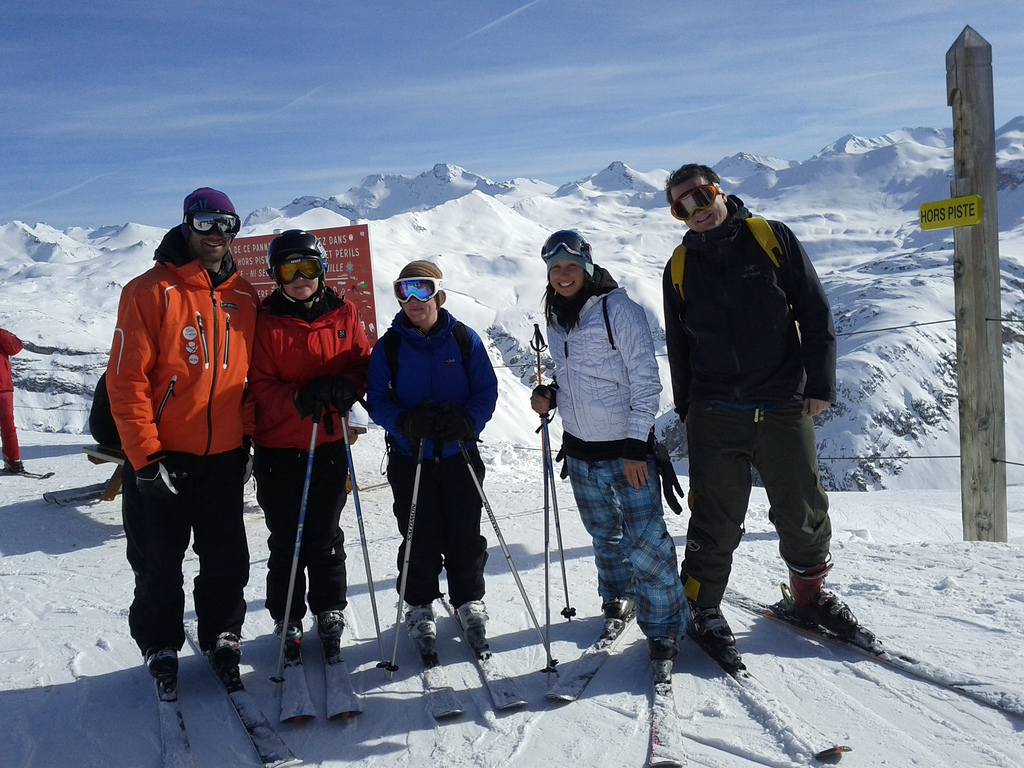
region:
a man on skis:
[108, 188, 301, 765]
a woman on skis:
[250, 226, 367, 727]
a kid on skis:
[364, 264, 523, 713]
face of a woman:
[544, 258, 583, 293]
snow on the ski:
[648, 671, 667, 767]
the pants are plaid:
[569, 453, 680, 644]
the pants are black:
[684, 438, 833, 582]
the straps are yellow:
[672, 211, 780, 292]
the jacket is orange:
[106, 226, 249, 471]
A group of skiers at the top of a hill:
[54, 161, 874, 678]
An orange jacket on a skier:
[106, 266, 252, 448]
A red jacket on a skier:
[257, 287, 366, 431]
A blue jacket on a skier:
[367, 307, 500, 456]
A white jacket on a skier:
[532, 290, 654, 445]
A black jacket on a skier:
[659, 211, 834, 401]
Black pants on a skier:
[118, 446, 252, 644]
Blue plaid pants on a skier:
[560, 449, 687, 640]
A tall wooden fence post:
[942, 22, 1012, 535]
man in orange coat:
[69, 129, 262, 702]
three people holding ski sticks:
[243, 229, 676, 670]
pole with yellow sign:
[888, 17, 1010, 559]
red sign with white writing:
[243, 227, 379, 330]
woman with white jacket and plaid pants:
[520, 205, 698, 686]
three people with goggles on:
[94, 205, 513, 717]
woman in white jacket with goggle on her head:
[502, 236, 680, 590]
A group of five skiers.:
[70, 164, 884, 766]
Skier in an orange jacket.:
[93, 186, 296, 766]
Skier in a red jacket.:
[250, 222, 388, 731]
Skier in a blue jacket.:
[340, 259, 537, 721]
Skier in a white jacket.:
[522, 218, 693, 766]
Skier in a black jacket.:
[655, 148, 1020, 760]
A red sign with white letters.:
[198, 215, 382, 356]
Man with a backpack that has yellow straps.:
[642, 151, 890, 660]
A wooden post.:
[914, 25, 1020, 541]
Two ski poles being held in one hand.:
[526, 322, 590, 684]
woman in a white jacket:
[498, 235, 715, 662]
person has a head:
[395, 258, 444, 325]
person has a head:
[544, 236, 590, 295]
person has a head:
[266, 233, 320, 303]